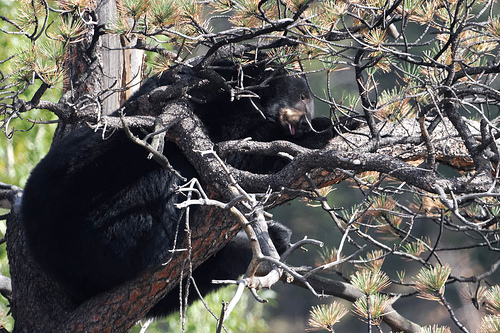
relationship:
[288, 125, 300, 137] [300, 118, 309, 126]
red tongue hanging down below nose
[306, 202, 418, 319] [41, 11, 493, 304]
flowers in tree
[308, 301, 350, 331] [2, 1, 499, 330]
flower on tree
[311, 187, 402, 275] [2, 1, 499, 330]
bunch on tree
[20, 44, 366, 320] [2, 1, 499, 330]
animal sleeping in tree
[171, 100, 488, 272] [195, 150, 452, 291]
bark on branches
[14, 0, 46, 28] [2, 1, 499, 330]
leaves on tree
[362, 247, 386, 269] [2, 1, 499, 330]
leaves on tree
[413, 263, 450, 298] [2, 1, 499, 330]
leaves on tree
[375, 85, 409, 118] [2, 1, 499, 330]
leaves on tree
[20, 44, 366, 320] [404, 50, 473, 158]
animal in tree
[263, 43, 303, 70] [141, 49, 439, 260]
leaves on branches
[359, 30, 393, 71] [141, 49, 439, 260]
leaves on branches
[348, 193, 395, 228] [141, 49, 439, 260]
leaves on branches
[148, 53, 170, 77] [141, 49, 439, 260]
leaves on branches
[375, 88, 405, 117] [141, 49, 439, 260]
leaves on branches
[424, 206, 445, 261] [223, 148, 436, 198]
sprig on branch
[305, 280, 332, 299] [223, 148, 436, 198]
sprig on branch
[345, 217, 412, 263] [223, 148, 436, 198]
sprig on branch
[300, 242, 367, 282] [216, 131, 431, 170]
sprig on branch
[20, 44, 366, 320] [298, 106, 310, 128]
animal has nose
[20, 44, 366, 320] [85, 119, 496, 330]
animal curled up on branch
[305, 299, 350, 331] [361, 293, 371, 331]
growth on branches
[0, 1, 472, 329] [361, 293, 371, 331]
growth on branches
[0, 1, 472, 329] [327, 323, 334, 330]
growth on branches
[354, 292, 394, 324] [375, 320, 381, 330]
growth on branches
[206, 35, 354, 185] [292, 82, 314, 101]
head has eye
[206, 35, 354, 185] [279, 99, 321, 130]
head has snout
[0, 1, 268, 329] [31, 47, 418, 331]
growth behind bear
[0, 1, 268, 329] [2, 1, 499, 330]
growth behind tree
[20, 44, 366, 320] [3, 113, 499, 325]
animal wedged in branch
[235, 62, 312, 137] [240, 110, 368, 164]
head laying on leg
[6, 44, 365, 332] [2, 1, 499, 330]
animal sitting in tree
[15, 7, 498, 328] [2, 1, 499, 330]
leaves on tree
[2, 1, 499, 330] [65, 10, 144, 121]
tree has stem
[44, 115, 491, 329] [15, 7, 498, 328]
branch has leaves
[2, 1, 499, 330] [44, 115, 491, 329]
tree has branch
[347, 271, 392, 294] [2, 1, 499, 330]
leaves on tree